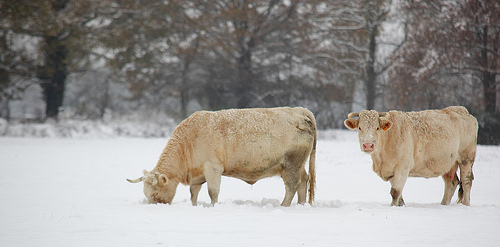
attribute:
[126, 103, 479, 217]
cows — walking, tan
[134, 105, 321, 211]
cow — white, brown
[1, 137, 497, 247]
snow — deep, white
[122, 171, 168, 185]
horns — white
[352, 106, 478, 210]
cow — standing, behind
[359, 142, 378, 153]
nose — pink, bright pink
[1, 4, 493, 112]
trees — bare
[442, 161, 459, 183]
udder — saggy, pink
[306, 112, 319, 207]
tail — long, shaggy, hanging, straight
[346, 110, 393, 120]
horns — curly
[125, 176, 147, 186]
horns — pointy, long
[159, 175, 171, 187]
ear — big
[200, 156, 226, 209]
left front leg — long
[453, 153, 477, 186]
patches — black, dark brown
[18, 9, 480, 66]
leaves — brown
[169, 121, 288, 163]
hair — beige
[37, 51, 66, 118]
trunks — dark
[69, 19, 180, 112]
branches — gray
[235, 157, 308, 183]
marks — black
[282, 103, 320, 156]
rump — flattened